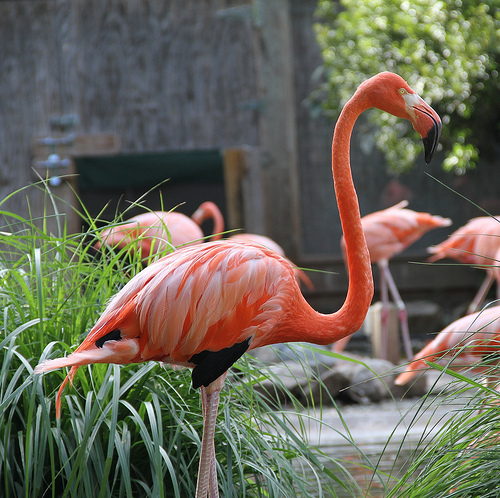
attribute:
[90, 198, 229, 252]
flamingo — pink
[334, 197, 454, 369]
flamingo — pink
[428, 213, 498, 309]
flamingo — pink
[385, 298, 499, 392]
flamingo — pink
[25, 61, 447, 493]
flamingo — pink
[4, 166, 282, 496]
water grass — long, green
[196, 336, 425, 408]
boulder — grey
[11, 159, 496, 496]
grass — tall 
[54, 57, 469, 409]
flamingo — real 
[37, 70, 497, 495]
flamingo — real 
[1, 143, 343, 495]
foilage — wide-bladed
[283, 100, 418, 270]
neck — pink 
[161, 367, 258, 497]
legs — long 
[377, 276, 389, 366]
leg — long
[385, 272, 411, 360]
leg — long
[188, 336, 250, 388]
black feathers — black , few 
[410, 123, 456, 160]
beak — black 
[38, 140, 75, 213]
light — fixture 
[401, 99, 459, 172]
beak — pink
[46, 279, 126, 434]
tail — pink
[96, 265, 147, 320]
feather — pink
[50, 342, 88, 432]
feather — pink